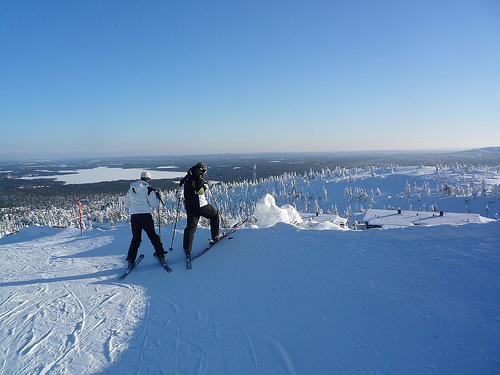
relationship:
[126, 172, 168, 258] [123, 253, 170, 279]
people wearing skis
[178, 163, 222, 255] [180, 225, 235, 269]
person wearing skis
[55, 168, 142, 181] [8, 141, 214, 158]
water in distance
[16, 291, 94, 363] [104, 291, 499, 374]
tracks are in snow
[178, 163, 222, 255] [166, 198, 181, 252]
person holding ski poles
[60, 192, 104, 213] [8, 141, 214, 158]
trees in distance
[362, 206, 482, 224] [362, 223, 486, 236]
roof of building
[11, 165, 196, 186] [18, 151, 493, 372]
lake at bottom of mountain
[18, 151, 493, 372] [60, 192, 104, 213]
mountain has trees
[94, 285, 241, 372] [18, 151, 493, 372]
shadow on mountain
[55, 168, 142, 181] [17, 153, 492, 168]
water in background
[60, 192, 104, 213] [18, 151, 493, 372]
trees on mountain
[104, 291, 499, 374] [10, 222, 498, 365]
snow covering ground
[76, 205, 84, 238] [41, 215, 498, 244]
safety pole on cliff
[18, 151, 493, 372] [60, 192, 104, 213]
mountain covered with trees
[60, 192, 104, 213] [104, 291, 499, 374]
trees are covered with snow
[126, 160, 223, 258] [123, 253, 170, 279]
people on skis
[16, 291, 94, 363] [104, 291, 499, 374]
tracks in snow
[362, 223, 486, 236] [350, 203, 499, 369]
building at foot of slope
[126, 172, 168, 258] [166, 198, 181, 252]
people have ski poles